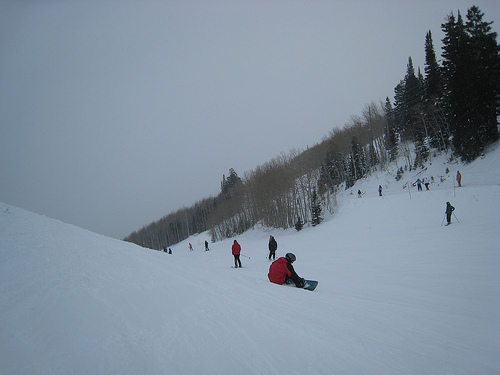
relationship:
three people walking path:
[406, 156, 471, 203] [344, 175, 484, 200]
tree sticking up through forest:
[216, 165, 248, 210] [120, 5, 499, 252]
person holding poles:
[442, 202, 455, 227] [450, 210, 459, 226]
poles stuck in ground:
[395, 180, 467, 228] [14, 145, 477, 371]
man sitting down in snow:
[266, 250, 315, 294] [2, 209, 462, 371]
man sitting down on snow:
[266, 250, 309, 288] [126, 243, 470, 364]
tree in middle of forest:
[215, 165, 247, 216] [86, 10, 479, 233]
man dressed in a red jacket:
[266, 250, 309, 288] [231, 242, 242, 257]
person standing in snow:
[228, 238, 242, 270] [2, 209, 462, 371]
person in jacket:
[228, 238, 242, 270] [224, 241, 240, 254]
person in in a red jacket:
[227, 232, 244, 267] [231, 242, 242, 257]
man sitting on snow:
[266, 250, 309, 288] [2, 209, 462, 371]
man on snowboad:
[266, 250, 309, 288] [292, 269, 318, 292]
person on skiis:
[228, 238, 242, 270] [222, 260, 248, 270]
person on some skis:
[442, 202, 457, 225] [443, 220, 453, 228]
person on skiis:
[442, 202, 455, 227] [438, 218, 455, 224]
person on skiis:
[351, 179, 370, 211] [375, 189, 384, 198]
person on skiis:
[370, 177, 389, 201] [196, 245, 212, 252]